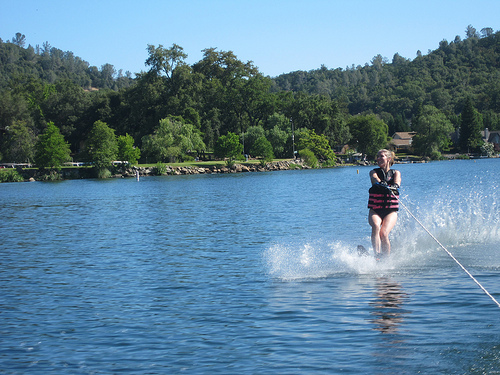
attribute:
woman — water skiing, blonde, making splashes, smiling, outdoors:
[363, 138, 428, 300]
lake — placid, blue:
[135, 293, 253, 331]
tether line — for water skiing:
[412, 209, 480, 292]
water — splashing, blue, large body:
[448, 162, 499, 184]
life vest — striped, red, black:
[363, 165, 408, 214]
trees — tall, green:
[145, 46, 283, 126]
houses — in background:
[394, 118, 500, 160]